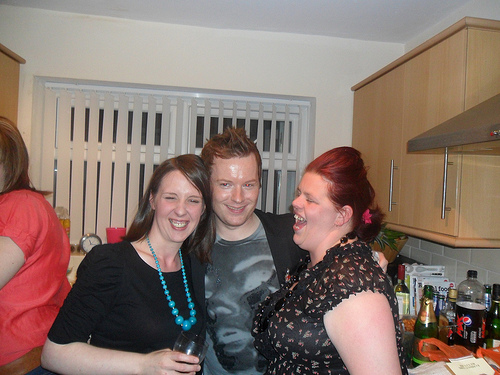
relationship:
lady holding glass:
[38, 153, 215, 373] [173, 336, 197, 359]